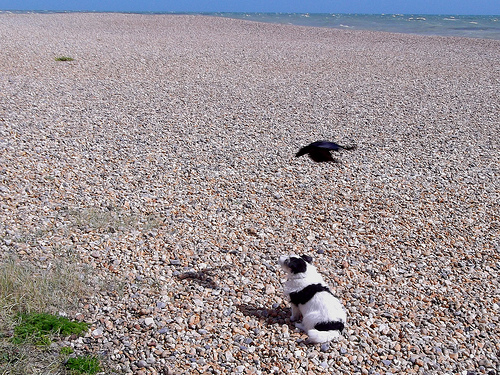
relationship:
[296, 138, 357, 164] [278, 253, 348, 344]
bird above dog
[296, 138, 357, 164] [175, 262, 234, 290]
bird has shadow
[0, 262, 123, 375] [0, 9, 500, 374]
weeds growing on beach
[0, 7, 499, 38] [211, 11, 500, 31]
ocean has waves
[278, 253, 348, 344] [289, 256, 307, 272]
dog has ear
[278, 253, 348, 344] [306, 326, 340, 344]
dog has tail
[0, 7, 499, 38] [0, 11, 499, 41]
ocean meets shoreline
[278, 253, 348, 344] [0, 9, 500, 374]
dog on top of beach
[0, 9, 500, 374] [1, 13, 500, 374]
beach has gravel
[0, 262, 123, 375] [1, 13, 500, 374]
weeds on gravel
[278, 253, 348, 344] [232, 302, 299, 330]
dog has shadow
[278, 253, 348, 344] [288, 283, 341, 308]
dog has stripe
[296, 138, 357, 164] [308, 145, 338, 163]
bird has wing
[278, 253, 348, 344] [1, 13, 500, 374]
dog on top of gravel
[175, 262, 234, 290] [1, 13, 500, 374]
shadow on gravel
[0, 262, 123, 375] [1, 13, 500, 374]
weeds growing near gravel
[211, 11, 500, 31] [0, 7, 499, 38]
waves on ocean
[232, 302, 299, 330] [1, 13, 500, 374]
shadow on top of gravel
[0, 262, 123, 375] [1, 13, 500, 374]
weeds surrounded by gravel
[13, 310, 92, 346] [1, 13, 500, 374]
grass near gravel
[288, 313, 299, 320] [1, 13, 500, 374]
paw on top of gravel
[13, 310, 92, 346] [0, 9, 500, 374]
grass near beach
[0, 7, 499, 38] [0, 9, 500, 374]
ocean near beach